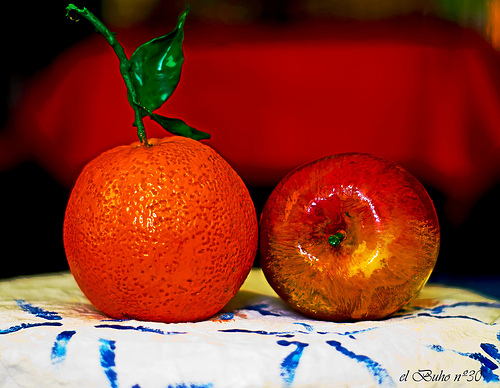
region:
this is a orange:
[56, 24, 261, 325]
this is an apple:
[262, 132, 445, 319]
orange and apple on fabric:
[20, 35, 470, 386]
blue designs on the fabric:
[28, 322, 487, 384]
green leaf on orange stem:
[111, 13, 213, 136]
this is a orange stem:
[69, 8, 163, 133]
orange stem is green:
[69, 1, 161, 132]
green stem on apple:
[317, 218, 353, 262]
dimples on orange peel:
[83, 165, 245, 293]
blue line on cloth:
[327, 338, 397, 386]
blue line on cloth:
[273, 335, 306, 383]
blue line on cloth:
[217, 325, 305, 339]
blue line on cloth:
[294, 319, 320, 337]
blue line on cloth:
[326, 322, 381, 342]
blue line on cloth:
[93, 320, 188, 338]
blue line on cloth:
[97, 336, 124, 386]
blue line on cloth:
[53, 329, 80, 362]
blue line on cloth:
[6, 322, 59, 339]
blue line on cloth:
[10, 293, 62, 321]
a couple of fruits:
[52, 27, 466, 386]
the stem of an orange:
[69, 7, 207, 136]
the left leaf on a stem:
[130, 13, 212, 110]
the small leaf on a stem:
[147, 84, 210, 141]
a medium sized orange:
[93, 152, 247, 316]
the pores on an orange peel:
[125, 191, 187, 229]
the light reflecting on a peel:
[116, 177, 152, 236]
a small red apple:
[252, 114, 450, 318]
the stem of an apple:
[310, 213, 352, 253]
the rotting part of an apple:
[330, 259, 375, 321]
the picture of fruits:
[7, 3, 492, 379]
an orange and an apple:
[58, 130, 450, 326]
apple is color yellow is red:
[258, 139, 446, 331]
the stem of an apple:
[317, 219, 354, 256]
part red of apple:
[258, 148, 439, 239]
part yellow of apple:
[276, 241, 435, 325]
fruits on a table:
[3, 122, 497, 385]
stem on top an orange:
[54, 4, 264, 338]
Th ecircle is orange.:
[63, 141, 258, 325]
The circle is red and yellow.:
[259, 152, 443, 327]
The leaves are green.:
[130, 7, 210, 141]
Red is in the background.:
[8, 18, 499, 216]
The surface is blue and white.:
[2, 271, 499, 385]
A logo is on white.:
[396, 363, 491, 380]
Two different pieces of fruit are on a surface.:
[60, 132, 440, 313]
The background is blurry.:
[1, 0, 498, 295]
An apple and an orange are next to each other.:
[62, 137, 442, 320]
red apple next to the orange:
[259, 145, 438, 327]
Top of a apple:
[302, 193, 369, 268]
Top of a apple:
[306, 199, 363, 263]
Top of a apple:
[303, 209, 374, 269]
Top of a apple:
[313, 208, 373, 266]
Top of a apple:
[312, 208, 368, 273]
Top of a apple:
[307, 203, 364, 267]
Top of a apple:
[312, 208, 372, 273]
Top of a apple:
[308, 213, 368, 267]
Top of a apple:
[301, 203, 363, 266]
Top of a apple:
[311, 204, 365, 264]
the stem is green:
[70, 3, 143, 139]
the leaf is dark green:
[126, 5, 182, 110]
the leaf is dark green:
[142, 105, 207, 135]